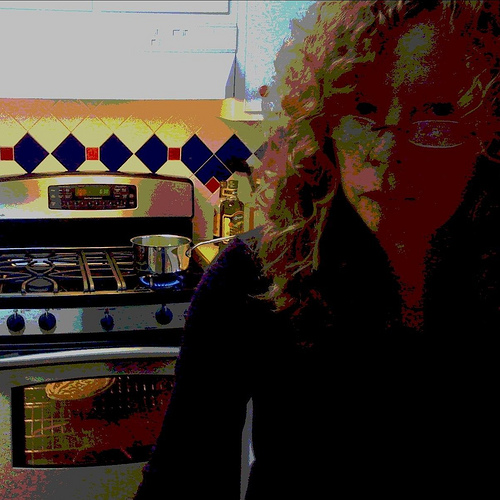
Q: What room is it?
A: It is a kitchen.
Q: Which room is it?
A: It is a kitchen.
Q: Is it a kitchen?
A: Yes, it is a kitchen.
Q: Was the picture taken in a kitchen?
A: Yes, it was taken in a kitchen.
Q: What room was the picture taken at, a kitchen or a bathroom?
A: It was taken at a kitchen.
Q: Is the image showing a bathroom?
A: No, the picture is showing a kitchen.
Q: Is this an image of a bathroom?
A: No, the picture is showing a kitchen.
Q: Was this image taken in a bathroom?
A: No, the picture was taken in a kitchen.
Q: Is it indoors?
A: Yes, it is indoors.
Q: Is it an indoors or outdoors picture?
A: It is indoors.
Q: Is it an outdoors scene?
A: No, it is indoors.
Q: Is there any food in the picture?
A: Yes, there is food.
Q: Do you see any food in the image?
A: Yes, there is food.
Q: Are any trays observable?
A: No, there are no trays.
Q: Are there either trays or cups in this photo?
A: No, there are no trays or cups.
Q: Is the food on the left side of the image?
A: Yes, the food is on the left of the image.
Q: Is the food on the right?
A: No, the food is on the left of the image.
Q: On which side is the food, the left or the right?
A: The food is on the left of the image.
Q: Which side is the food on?
A: The food is on the left of the image.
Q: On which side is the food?
A: The food is on the left of the image.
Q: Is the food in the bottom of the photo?
A: Yes, the food is in the bottom of the image.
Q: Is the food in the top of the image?
A: No, the food is in the bottom of the image.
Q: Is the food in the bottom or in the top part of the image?
A: The food is in the bottom of the image.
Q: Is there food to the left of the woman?
A: Yes, there is food to the left of the woman.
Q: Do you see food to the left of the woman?
A: Yes, there is food to the left of the woman.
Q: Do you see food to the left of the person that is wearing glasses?
A: Yes, there is food to the left of the woman.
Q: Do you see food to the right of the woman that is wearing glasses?
A: No, the food is to the left of the woman.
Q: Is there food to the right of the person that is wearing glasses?
A: No, the food is to the left of the woman.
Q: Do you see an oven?
A: Yes, there is an oven.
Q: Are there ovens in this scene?
A: Yes, there is an oven.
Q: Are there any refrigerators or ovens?
A: Yes, there is an oven.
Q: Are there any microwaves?
A: No, there are no microwaves.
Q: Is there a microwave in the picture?
A: No, there are no microwaves.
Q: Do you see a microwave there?
A: No, there are no microwaves.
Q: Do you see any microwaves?
A: No, there are no microwaves.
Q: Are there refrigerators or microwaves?
A: No, there are no microwaves or refrigerators.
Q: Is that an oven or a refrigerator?
A: That is an oven.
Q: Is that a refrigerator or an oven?
A: That is an oven.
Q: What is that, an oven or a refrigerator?
A: That is an oven.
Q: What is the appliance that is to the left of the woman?
A: The appliance is an oven.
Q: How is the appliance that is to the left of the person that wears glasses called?
A: The appliance is an oven.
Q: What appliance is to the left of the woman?
A: The appliance is an oven.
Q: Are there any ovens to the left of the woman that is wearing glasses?
A: Yes, there is an oven to the left of the woman.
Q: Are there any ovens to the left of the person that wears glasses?
A: Yes, there is an oven to the left of the woman.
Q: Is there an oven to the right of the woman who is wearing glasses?
A: No, the oven is to the left of the woman.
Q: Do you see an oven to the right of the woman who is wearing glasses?
A: No, the oven is to the left of the woman.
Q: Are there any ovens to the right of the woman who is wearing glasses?
A: No, the oven is to the left of the woman.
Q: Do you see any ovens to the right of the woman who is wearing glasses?
A: No, the oven is to the left of the woman.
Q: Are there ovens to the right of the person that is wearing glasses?
A: No, the oven is to the left of the woman.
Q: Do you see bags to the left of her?
A: No, there is an oven to the left of the woman.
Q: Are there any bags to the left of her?
A: No, there is an oven to the left of the woman.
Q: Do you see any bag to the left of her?
A: No, there is an oven to the left of the woman.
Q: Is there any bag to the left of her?
A: No, there is an oven to the left of the woman.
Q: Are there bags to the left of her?
A: No, there is an oven to the left of the woman.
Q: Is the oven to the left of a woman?
A: Yes, the oven is to the left of a woman.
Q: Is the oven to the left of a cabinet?
A: No, the oven is to the left of a woman.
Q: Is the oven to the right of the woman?
A: No, the oven is to the left of the woman.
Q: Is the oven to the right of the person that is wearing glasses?
A: No, the oven is to the left of the woman.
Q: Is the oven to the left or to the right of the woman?
A: The oven is to the left of the woman.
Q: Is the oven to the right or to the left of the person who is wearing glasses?
A: The oven is to the left of the woman.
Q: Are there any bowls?
A: No, there are no bowls.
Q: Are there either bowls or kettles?
A: No, there are no bowls or kettles.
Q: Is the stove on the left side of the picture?
A: Yes, the stove is on the left of the image.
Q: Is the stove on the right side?
A: No, the stove is on the left of the image.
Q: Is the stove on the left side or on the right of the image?
A: The stove is on the left of the image.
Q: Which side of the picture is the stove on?
A: The stove is on the left of the image.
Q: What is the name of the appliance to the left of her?
A: The appliance is a stove.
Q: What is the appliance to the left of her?
A: The appliance is a stove.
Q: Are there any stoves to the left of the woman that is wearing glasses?
A: Yes, there is a stove to the left of the woman.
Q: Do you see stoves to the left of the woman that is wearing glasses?
A: Yes, there is a stove to the left of the woman.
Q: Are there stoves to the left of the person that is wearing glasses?
A: Yes, there is a stove to the left of the woman.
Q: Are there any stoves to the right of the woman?
A: No, the stove is to the left of the woman.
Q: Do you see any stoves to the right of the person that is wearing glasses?
A: No, the stove is to the left of the woman.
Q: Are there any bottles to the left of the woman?
A: No, there is a stove to the left of the woman.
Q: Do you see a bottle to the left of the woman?
A: No, there is a stove to the left of the woman.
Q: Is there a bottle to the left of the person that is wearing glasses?
A: No, there is a stove to the left of the woman.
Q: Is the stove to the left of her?
A: Yes, the stove is to the left of the woman.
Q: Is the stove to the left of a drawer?
A: No, the stove is to the left of the woman.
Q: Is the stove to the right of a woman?
A: No, the stove is to the left of a woman.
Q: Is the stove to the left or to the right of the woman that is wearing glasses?
A: The stove is to the left of the woman.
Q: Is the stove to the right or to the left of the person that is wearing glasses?
A: The stove is to the left of the woman.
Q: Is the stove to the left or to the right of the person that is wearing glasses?
A: The stove is to the left of the woman.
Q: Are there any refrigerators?
A: No, there are no refrigerators.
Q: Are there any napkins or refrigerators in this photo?
A: No, there are no refrigerators or napkins.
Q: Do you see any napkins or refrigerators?
A: No, there are no refrigerators or napkins.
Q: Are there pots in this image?
A: Yes, there is a pot.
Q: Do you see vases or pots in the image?
A: Yes, there is a pot.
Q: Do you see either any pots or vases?
A: Yes, there is a pot.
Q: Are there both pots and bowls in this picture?
A: No, there is a pot but no bowls.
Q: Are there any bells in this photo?
A: No, there are no bells.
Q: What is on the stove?
A: The pot is on the stove.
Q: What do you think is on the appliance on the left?
A: The pot is on the stove.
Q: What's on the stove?
A: The pot is on the stove.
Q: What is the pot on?
A: The pot is on the stove.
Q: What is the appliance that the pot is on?
A: The appliance is a stove.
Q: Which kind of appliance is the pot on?
A: The pot is on the stove.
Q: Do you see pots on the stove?
A: Yes, there is a pot on the stove.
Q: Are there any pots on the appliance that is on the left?
A: Yes, there is a pot on the stove.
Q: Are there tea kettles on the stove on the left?
A: No, there is a pot on the stove.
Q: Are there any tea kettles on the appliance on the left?
A: No, there is a pot on the stove.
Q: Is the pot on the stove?
A: Yes, the pot is on the stove.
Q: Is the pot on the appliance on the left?
A: Yes, the pot is on the stove.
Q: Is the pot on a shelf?
A: No, the pot is on the stove.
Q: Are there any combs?
A: No, there are no combs.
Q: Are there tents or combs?
A: No, there are no combs or tents.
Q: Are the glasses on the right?
A: Yes, the glasses are on the right of the image.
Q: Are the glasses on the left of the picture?
A: No, the glasses are on the right of the image.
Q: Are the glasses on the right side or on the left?
A: The glasses are on the right of the image.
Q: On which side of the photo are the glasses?
A: The glasses are on the right of the image.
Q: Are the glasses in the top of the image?
A: Yes, the glasses are in the top of the image.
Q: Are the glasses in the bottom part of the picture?
A: No, the glasses are in the top of the image.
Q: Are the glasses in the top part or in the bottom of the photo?
A: The glasses are in the top of the image.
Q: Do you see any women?
A: Yes, there is a woman.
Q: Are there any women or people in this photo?
A: Yes, there is a woman.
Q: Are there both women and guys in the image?
A: No, there is a woman but no guys.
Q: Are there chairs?
A: No, there are no chairs.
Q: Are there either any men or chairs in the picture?
A: No, there are no chairs or men.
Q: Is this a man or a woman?
A: This is a woman.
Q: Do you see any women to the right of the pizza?
A: Yes, there is a woman to the right of the pizza.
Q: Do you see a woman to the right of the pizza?
A: Yes, there is a woman to the right of the pizza.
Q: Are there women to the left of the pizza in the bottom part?
A: No, the woman is to the right of the pizza.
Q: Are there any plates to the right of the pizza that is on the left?
A: No, there is a woman to the right of the pizza.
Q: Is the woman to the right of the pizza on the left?
A: Yes, the woman is to the right of the pizza.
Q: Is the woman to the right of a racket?
A: No, the woman is to the right of the pizza.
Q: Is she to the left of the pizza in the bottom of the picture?
A: No, the woman is to the right of the pizza.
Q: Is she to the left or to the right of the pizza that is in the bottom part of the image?
A: The woman is to the right of the pizza.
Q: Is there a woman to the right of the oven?
A: Yes, there is a woman to the right of the oven.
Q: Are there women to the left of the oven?
A: No, the woman is to the right of the oven.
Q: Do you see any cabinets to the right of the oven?
A: No, there is a woman to the right of the oven.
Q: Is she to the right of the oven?
A: Yes, the woman is to the right of the oven.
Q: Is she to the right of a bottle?
A: No, the woman is to the right of the oven.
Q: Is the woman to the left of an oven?
A: No, the woman is to the right of an oven.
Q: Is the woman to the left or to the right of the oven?
A: The woman is to the right of the oven.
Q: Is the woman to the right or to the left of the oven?
A: The woman is to the right of the oven.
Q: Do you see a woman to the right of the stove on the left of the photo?
A: Yes, there is a woman to the right of the stove.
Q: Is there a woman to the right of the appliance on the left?
A: Yes, there is a woman to the right of the stove.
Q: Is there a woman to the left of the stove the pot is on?
A: No, the woman is to the right of the stove.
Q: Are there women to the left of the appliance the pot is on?
A: No, the woman is to the right of the stove.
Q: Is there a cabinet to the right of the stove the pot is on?
A: No, there is a woman to the right of the stove.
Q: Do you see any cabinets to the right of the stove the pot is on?
A: No, there is a woman to the right of the stove.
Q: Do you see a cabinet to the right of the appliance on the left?
A: No, there is a woman to the right of the stove.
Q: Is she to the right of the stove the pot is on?
A: Yes, the woman is to the right of the stove.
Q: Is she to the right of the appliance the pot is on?
A: Yes, the woman is to the right of the stove.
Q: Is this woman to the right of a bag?
A: No, the woman is to the right of the stove.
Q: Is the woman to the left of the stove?
A: No, the woman is to the right of the stove.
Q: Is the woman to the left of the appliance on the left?
A: No, the woman is to the right of the stove.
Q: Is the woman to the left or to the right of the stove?
A: The woman is to the right of the stove.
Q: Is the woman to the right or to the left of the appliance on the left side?
A: The woman is to the right of the stove.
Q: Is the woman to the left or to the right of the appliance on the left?
A: The woman is to the right of the stove.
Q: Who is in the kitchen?
A: The woman is in the kitchen.